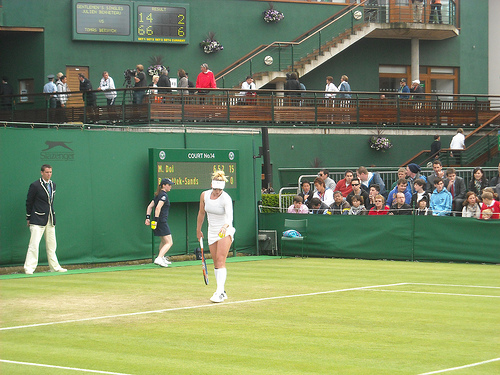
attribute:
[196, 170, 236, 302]
tennis player — blonde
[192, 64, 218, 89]
top — red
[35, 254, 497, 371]
court — green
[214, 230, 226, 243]
tennis ball — yellow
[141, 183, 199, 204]
hat — dark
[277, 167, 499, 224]
crowd — small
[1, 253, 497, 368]
tennis court — green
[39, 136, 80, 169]
logo — black